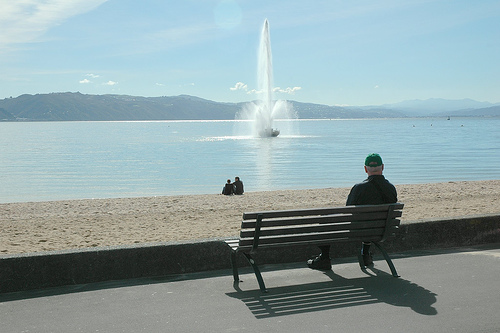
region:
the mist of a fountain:
[237, 99, 281, 131]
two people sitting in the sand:
[220, 171, 260, 205]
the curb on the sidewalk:
[28, 241, 99, 289]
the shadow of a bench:
[251, 289, 318, 321]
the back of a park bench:
[244, 202, 301, 242]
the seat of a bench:
[212, 231, 247, 253]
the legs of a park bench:
[217, 253, 269, 291]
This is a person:
[335, 134, 434, 307]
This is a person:
[230, 167, 250, 203]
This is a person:
[216, 170, 234, 200]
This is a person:
[326, 142, 406, 322]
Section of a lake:
[83, 116, 193, 179]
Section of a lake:
[6, 142, 86, 193]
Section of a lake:
[314, 117, 431, 156]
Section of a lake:
[245, 124, 315, 189]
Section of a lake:
[29, 136, 148, 203]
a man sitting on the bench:
[212, 142, 417, 301]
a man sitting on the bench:
[197, 156, 439, 301]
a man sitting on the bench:
[213, 142, 413, 294]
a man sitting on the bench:
[212, 135, 419, 315]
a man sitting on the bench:
[215, 141, 422, 324]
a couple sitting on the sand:
[211, 168, 251, 198]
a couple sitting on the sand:
[211, 171, 258, 201]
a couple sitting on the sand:
[208, 164, 254, 201]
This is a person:
[343, 128, 421, 285]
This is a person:
[220, 172, 233, 202]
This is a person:
[347, 139, 419, 291]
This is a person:
[220, 172, 239, 198]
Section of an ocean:
[54, 140, 128, 179]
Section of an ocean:
[110, 117, 217, 177]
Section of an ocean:
[283, 135, 343, 190]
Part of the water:
[120, 155, 154, 172]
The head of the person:
[363, 150, 385, 175]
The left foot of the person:
[303, 253, 334, 271]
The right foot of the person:
[359, 250, 375, 267]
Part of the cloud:
[40, 9, 60, 22]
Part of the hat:
[371, 155, 378, 158]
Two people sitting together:
[221, 175, 246, 197]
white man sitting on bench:
[304, 153, 399, 272]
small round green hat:
[361, 151, 382, 167]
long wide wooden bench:
[224, 201, 408, 291]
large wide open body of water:
[0, 119, 499, 200]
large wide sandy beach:
[0, 179, 499, 251]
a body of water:
[61, 111, 213, 163]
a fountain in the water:
[186, 43, 346, 198]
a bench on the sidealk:
[302, 178, 415, 287]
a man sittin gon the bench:
[331, 144, 416, 256]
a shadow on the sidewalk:
[361, 256, 438, 331]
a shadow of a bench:
[221, 253, 411, 328]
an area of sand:
[26, 189, 167, 250]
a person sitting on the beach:
[216, 161, 256, 220]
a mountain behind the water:
[143, 106, 158, 116]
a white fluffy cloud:
[23, 0, 65, 35]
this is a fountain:
[212, 45, 312, 141]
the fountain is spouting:
[210, 80, 367, 214]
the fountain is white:
[195, 28, 302, 105]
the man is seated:
[237, 133, 436, 230]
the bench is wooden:
[254, 185, 401, 304]